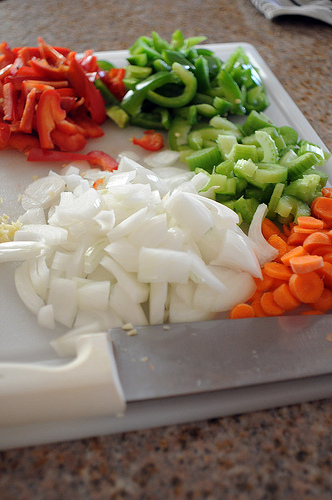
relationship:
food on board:
[19, 32, 299, 321] [38, 28, 316, 414]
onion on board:
[0, 155, 279, 358] [10, 305, 24, 333]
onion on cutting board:
[0, 155, 279, 358] [1, 38, 330, 455]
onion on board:
[0, 155, 279, 358] [1, 40, 329, 453]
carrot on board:
[230, 186, 332, 319] [1, 40, 329, 453]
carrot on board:
[296, 214, 323, 230] [1, 40, 329, 453]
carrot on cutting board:
[230, 186, 332, 319] [216, 29, 288, 87]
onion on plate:
[5, 150, 279, 354] [1, 53, 321, 381]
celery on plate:
[251, 165, 295, 180] [1, 53, 321, 381]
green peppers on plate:
[92, 27, 269, 152] [0, 24, 332, 199]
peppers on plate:
[7, 37, 115, 168] [1, 53, 321, 381]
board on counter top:
[0, 42, 332, 451] [167, 436, 322, 492]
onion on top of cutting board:
[0, 155, 279, 358] [7, 52, 295, 245]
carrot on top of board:
[230, 186, 332, 319] [0, 42, 332, 451]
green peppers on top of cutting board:
[92, 25, 272, 154] [1, 38, 330, 455]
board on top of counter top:
[4, 45, 324, 339] [0, 451, 332, 500]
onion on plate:
[0, 155, 279, 358] [1, 53, 321, 381]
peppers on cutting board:
[0, 36, 164, 172] [5, 38, 319, 366]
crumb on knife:
[118, 322, 132, 330] [5, 312, 329, 434]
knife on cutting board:
[7, 321, 314, 432] [5, 38, 319, 366]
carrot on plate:
[230, 186, 332, 319] [9, 152, 27, 200]